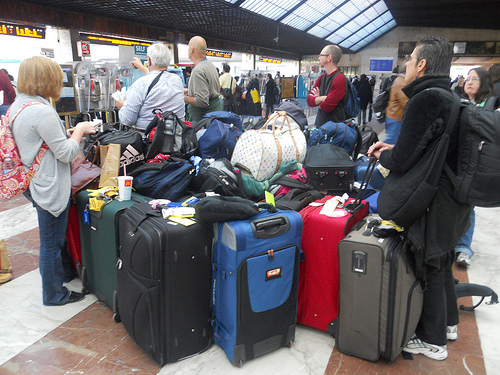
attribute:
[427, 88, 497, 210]
backpack — big, black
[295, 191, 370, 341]
suitcase — red, large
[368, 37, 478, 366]
man — standing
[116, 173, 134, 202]
cup — paper, soda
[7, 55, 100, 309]
woman — blonde, standing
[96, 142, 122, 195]
bag — paper, brown, mcdonald's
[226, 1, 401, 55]
window — partitioned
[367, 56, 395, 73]
sign — blue, white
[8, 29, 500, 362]
people — waiting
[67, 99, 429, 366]
luggage — pile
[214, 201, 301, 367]
luggage — blue, black, gray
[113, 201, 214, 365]
luggage — black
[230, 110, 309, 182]
purse — white, black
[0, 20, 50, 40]
sign — electronic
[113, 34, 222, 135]
men — talking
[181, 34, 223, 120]
man — older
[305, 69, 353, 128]
shirt — red, black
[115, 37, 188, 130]
man — pointing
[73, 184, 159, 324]
suitcase — green